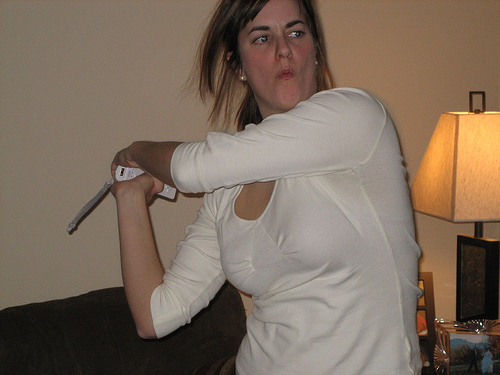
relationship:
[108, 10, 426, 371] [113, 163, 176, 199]
woman playing controller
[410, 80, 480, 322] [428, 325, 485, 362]
lamp on a table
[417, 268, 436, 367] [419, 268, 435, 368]
edge of a chair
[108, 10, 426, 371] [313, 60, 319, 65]
woman wearing earring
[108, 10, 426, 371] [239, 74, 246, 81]
woman wearing earring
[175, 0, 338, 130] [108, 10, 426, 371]
hair on woman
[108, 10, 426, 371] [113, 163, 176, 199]
woman holding controller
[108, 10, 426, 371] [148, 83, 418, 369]
woman wearing shirt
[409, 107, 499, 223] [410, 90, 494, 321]
shade on lamp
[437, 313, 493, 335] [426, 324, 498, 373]
ashtray on table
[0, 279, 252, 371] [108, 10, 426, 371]
sofa behind woman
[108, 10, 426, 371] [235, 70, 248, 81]
woman wearing earring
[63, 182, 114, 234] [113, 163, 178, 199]
strap on controller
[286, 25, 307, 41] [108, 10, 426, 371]
eye on woman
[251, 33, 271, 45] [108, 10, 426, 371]
eye on woman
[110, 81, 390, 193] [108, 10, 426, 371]
arm on woman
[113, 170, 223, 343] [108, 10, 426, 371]
arm on woman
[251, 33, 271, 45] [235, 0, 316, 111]
eye on face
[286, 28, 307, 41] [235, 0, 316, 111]
eye on face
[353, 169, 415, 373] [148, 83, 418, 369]
line on shirt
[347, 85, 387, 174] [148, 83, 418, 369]
line on shirt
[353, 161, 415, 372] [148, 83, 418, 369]
line on shirt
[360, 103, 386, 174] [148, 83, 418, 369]
line on shirt